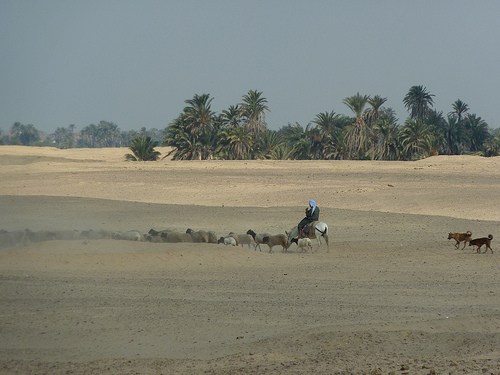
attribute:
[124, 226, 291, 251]
sheep — walking, white, black, tan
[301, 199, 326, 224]
man — riding, blue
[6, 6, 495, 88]
sky — blue, cloudless, gray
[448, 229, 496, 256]
dogs — brown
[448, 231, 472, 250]
dog — brown, walking, invisible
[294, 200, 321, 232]
person — riding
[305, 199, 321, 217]
headscarf — blue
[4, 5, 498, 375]
desert — bare